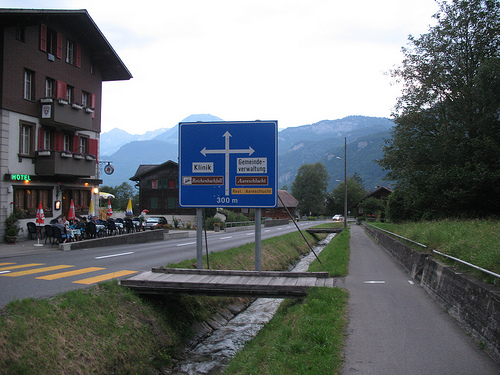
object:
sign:
[3, 172, 37, 182]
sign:
[103, 163, 115, 174]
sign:
[41, 97, 53, 124]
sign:
[179, 120, 279, 209]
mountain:
[96, 113, 396, 197]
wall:
[363, 226, 498, 365]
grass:
[368, 216, 499, 284]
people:
[57, 218, 69, 240]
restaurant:
[0, 7, 133, 249]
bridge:
[124, 267, 335, 298]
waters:
[171, 233, 336, 374]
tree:
[376, 0, 499, 222]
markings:
[73, 268, 138, 284]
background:
[0, 0, 499, 373]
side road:
[340, 223, 500, 374]